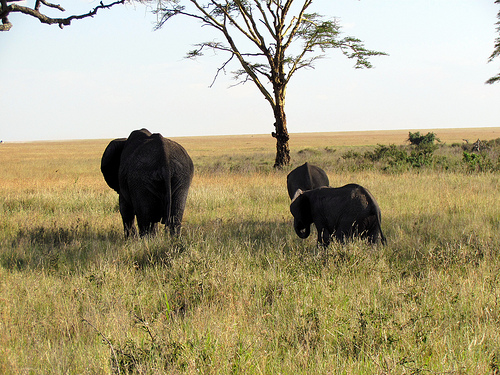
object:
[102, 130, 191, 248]
elephant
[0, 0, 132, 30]
tree branch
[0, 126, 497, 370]
wilderness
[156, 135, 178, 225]
tail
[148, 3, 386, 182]
tree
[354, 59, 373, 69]
leaves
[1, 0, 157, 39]
gnarled branch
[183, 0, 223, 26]
gnarled branch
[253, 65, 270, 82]
gnarled branch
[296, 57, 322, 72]
gnarled branch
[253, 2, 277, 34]
gnarled branch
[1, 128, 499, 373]
plain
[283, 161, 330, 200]
elephant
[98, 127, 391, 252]
elephants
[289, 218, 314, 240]
trunk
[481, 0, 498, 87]
leafy twigs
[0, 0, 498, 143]
sky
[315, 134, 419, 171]
brown grass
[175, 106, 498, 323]
savanah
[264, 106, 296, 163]
trunk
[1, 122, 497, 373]
ground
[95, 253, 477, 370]
grass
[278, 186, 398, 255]
elephant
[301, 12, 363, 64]
leaves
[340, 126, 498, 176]
vegetation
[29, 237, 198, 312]
shadow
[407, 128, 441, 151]
vegetation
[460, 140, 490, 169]
vegetation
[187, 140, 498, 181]
patch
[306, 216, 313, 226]
mouth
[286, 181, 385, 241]
profile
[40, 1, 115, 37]
branch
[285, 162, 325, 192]
backside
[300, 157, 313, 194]
tail